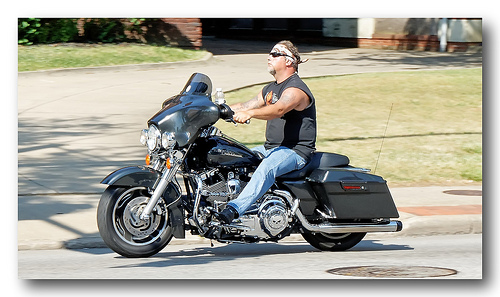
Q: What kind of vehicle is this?
A: A motorcycle.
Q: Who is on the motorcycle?
A: A man.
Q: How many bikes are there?
A: One.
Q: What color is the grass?
A: Green.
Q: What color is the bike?
A: Black.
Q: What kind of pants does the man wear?
A: Jeans.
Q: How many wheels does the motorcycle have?
A: Two.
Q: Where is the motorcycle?
A: On the road.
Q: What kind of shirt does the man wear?
A: Sleeveless.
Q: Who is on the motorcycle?
A: A man.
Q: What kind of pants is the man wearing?
A: Jeans.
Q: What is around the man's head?
A: Headband.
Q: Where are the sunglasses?
A: On the man's eyes.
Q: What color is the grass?
A: Tan and green.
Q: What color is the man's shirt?
A: Black.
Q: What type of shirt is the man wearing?
A: Sleeveless.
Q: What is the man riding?
A: A motorcycle.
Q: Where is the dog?
A: There isn't one.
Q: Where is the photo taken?
A: Daytime.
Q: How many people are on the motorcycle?
A: One.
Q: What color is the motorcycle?
A: Black.